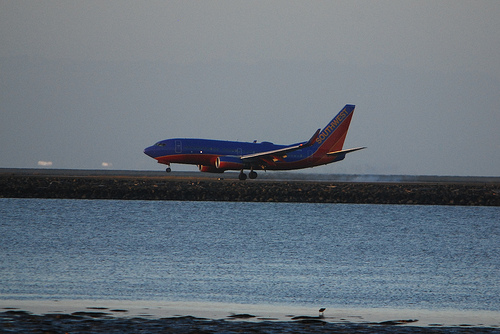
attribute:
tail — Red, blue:
[321, 100, 353, 145]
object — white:
[95, 155, 117, 176]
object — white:
[32, 151, 54, 171]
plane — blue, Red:
[147, 97, 364, 187]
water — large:
[1, 205, 498, 310]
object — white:
[35, 157, 63, 171]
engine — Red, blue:
[211, 144, 249, 172]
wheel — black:
[237, 165, 257, 183]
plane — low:
[141, 102, 367, 182]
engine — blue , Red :
[205, 150, 250, 181]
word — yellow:
[321, 101, 359, 147]